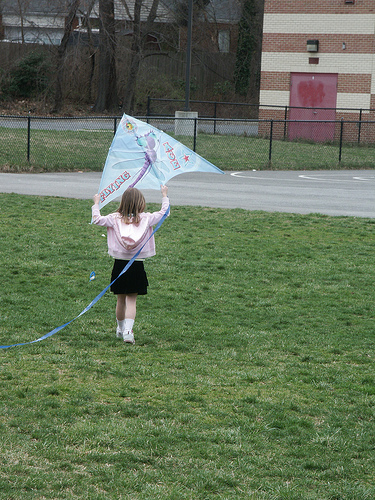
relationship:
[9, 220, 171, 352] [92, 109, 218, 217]
tail of kite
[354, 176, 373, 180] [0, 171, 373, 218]
circles on asphalt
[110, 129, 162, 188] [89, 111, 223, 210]
dragonfly on kite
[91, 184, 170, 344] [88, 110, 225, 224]
girl holding kite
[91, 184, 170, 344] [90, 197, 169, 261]
girl wearing jacket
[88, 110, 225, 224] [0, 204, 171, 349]
kite has tail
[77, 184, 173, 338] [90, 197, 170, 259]
girl wearing jacket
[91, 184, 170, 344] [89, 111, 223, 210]
girl carrying kite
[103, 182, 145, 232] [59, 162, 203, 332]
hair of girl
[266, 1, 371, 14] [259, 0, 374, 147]
brick in building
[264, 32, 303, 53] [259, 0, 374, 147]
brick in building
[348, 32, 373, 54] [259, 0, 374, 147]
brick in building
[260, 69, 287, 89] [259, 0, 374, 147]
brick in building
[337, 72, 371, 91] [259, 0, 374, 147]
brick in building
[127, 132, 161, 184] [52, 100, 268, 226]
dragonfly on kite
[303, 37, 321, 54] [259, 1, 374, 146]
light on wall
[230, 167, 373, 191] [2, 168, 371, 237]
lines on basketball court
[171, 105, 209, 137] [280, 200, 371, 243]
pole on ground